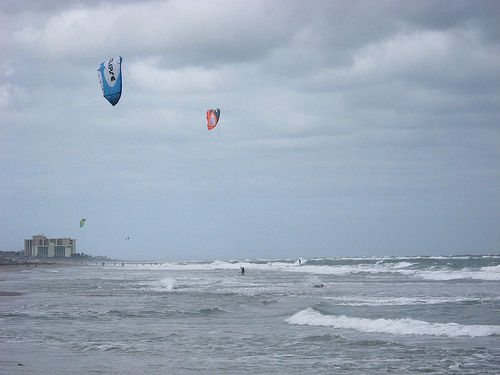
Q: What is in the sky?
A: Sails.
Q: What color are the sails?
A: Red and blue.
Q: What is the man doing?
A: Windsurfing.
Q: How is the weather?
A: Overcast.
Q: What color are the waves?
A: White.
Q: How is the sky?
A: Cloudy.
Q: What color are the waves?
A: White.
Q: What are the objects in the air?
A: Sails.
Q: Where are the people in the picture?
A: In the ocean.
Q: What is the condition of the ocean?
A: Rough.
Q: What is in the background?
A: Building.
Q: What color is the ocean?
A: Gray.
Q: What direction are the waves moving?
A: Right to left.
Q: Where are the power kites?
A: In the sky.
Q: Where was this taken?
A: Ocean.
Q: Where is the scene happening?
A: Over water.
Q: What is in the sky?
A: Kites.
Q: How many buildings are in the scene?
A: One.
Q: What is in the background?
A: A building.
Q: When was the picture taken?
A: Daytime.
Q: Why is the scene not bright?
A: The clouds.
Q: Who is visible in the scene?
A: Two people.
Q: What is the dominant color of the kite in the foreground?
A: Blue.